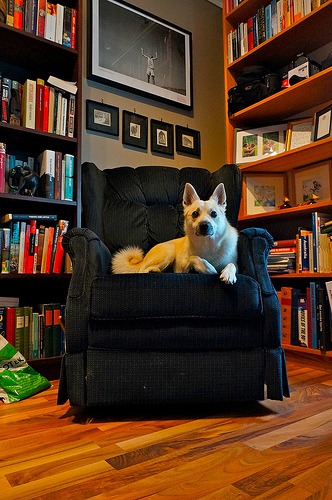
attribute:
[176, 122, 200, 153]
picture — black framed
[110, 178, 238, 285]
dog — white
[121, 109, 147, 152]
framed picture — black framed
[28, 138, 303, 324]
recliner — black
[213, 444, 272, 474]
flooring — light brown, hard wood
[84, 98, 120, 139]
frame — black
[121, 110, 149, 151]
frame — black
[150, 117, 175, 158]
frame — black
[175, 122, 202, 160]
frame — black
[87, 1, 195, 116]
frame — black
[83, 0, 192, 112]
picture — black framed